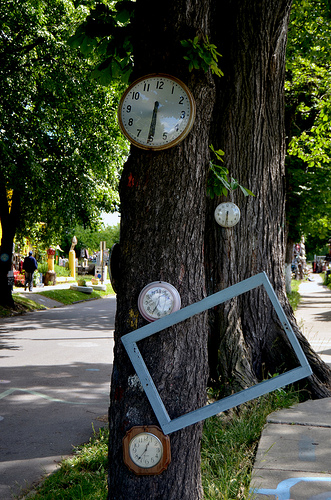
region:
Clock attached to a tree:
[107, 50, 212, 165]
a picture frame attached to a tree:
[107, 257, 320, 440]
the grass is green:
[30, 367, 271, 498]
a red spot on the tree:
[109, 159, 157, 216]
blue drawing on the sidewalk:
[238, 443, 329, 498]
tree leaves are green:
[1, 10, 126, 307]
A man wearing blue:
[17, 248, 43, 292]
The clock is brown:
[113, 416, 180, 476]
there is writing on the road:
[0, 365, 104, 459]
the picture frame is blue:
[111, 263, 315, 437]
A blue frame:
[123, 269, 318, 420]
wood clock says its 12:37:
[122, 423, 177, 476]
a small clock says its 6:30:
[213, 198, 242, 231]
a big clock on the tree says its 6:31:
[116, 72, 200, 152]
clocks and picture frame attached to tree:
[117, 66, 249, 498]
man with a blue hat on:
[22, 248, 39, 292]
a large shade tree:
[4, 58, 124, 336]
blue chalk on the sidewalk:
[253, 466, 324, 499]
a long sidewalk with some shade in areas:
[254, 271, 330, 479]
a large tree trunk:
[203, 256, 330, 400]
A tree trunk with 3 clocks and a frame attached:
[121, 78, 196, 491]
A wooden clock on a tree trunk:
[120, 421, 178, 478]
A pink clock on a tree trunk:
[135, 276, 183, 323]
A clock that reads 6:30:
[110, 67, 200, 157]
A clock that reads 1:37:
[118, 423, 174, 480]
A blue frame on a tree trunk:
[118, 269, 318, 434]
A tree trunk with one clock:
[215, 35, 287, 342]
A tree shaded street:
[2, 274, 115, 496]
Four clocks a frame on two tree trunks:
[115, 57, 303, 499]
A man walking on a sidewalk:
[13, 243, 58, 299]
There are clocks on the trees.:
[113, 74, 246, 480]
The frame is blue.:
[118, 285, 314, 438]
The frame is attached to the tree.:
[121, 279, 306, 423]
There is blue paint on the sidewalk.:
[247, 437, 330, 496]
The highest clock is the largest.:
[116, 66, 199, 157]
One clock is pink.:
[137, 277, 183, 325]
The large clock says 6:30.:
[116, 71, 197, 155]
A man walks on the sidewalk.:
[15, 246, 48, 296]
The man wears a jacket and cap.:
[15, 245, 47, 295]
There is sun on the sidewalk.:
[1, 298, 117, 379]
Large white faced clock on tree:
[115, 66, 196, 151]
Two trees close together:
[114, 26, 328, 482]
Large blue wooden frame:
[114, 266, 318, 434]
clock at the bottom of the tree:
[118, 418, 182, 478]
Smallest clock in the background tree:
[208, 194, 246, 230]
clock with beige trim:
[132, 270, 184, 326]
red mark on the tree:
[117, 164, 148, 200]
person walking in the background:
[16, 243, 43, 296]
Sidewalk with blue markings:
[233, 447, 329, 498]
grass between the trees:
[16, 370, 314, 495]